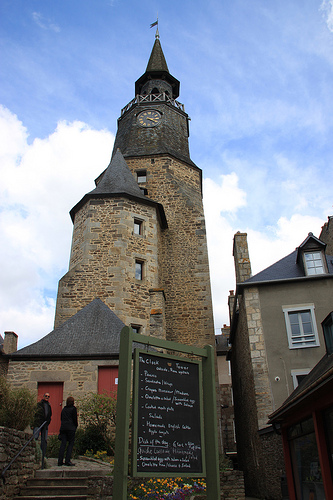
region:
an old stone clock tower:
[62, 13, 221, 346]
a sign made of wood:
[112, 322, 222, 497]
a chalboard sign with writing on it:
[131, 347, 209, 484]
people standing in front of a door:
[26, 384, 103, 474]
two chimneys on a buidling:
[216, 220, 255, 313]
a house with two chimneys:
[214, 210, 331, 419]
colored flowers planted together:
[127, 474, 209, 498]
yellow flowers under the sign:
[135, 478, 171, 495]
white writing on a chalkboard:
[141, 353, 198, 470]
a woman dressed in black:
[59, 392, 81, 465]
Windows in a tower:
[131, 215, 149, 290]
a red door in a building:
[29, 378, 64, 439]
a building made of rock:
[10, 341, 101, 443]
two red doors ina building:
[29, 361, 123, 439]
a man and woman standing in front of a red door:
[35, 389, 78, 466]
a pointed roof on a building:
[15, 294, 166, 358]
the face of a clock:
[134, 109, 165, 130]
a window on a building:
[280, 303, 322, 349]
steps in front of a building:
[15, 464, 102, 499]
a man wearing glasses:
[43, 393, 50, 399]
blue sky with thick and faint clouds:
[3, 2, 329, 350]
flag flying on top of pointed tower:
[118, 88, 184, 127]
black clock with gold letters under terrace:
[115, 90, 181, 125]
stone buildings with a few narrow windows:
[41, 151, 207, 342]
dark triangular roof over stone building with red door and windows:
[3, 286, 144, 450]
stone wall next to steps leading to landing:
[0, 421, 102, 485]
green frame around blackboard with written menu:
[110, 318, 215, 490]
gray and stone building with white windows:
[230, 208, 322, 418]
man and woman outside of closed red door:
[30, 377, 107, 471]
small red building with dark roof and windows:
[279, 314, 328, 493]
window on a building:
[278, 299, 322, 350]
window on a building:
[291, 370, 309, 386]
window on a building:
[301, 247, 329, 279]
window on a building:
[130, 322, 143, 334]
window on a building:
[130, 256, 144, 279]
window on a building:
[133, 215, 142, 235]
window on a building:
[135, 170, 146, 184]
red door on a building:
[34, 380, 63, 438]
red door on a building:
[95, 363, 123, 400]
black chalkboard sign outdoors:
[134, 352, 207, 482]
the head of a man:
[11, 376, 75, 432]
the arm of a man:
[32, 409, 53, 432]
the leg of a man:
[31, 411, 63, 458]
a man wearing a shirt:
[28, 388, 65, 442]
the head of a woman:
[62, 389, 89, 411]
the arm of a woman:
[58, 394, 102, 437]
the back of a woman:
[57, 373, 93, 421]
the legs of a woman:
[54, 425, 98, 467]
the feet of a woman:
[47, 427, 105, 479]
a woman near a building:
[25, 381, 121, 480]